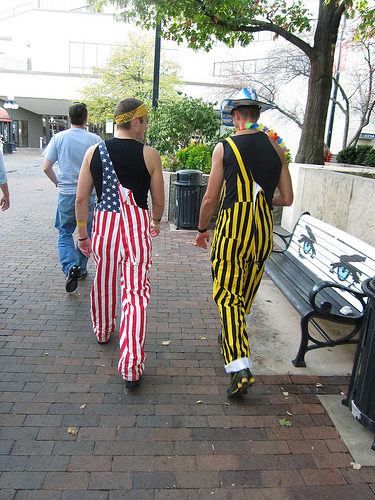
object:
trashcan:
[171, 167, 208, 232]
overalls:
[87, 136, 153, 383]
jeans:
[54, 192, 97, 294]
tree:
[202, 10, 367, 153]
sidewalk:
[7, 158, 373, 498]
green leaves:
[156, 99, 216, 137]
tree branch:
[240, 13, 312, 55]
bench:
[281, 197, 366, 308]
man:
[191, 82, 292, 401]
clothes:
[208, 134, 281, 367]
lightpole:
[125, 25, 181, 106]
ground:
[323, 124, 355, 158]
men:
[73, 75, 312, 413]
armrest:
[307, 280, 367, 314]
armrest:
[269, 231, 290, 246]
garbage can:
[160, 169, 198, 229]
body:
[75, 99, 165, 390]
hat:
[215, 88, 272, 106]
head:
[210, 79, 271, 130]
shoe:
[57, 264, 93, 308]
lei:
[233, 121, 292, 163]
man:
[72, 97, 164, 390]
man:
[39, 99, 103, 294]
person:
[40, 102, 103, 292]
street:
[4, 150, 44, 163]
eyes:
[292, 215, 365, 287]